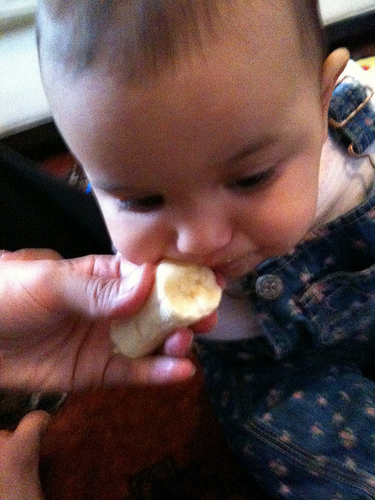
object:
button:
[257, 275, 281, 300]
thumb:
[40, 259, 153, 319]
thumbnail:
[115, 263, 151, 292]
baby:
[36, 2, 373, 497]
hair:
[35, 1, 327, 90]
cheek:
[253, 184, 316, 253]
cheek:
[103, 209, 170, 266]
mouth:
[212, 241, 257, 275]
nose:
[176, 189, 234, 253]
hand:
[3, 254, 226, 386]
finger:
[100, 349, 197, 386]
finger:
[158, 324, 194, 358]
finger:
[188, 304, 222, 333]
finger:
[210, 272, 226, 292]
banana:
[111, 257, 221, 360]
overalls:
[190, 78, 369, 496]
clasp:
[207, 261, 285, 302]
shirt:
[107, 57, 372, 336]